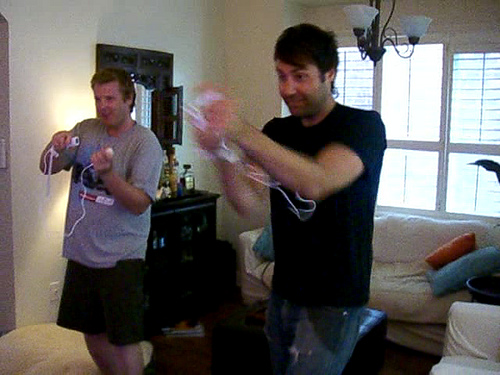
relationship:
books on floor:
[156, 311, 220, 356] [151, 319, 292, 369]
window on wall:
[342, 41, 499, 217] [0, 0, 275, 254]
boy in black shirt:
[39, 66, 164, 374] [254, 100, 389, 310]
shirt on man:
[41, 122, 166, 262] [36, 66, 169, 373]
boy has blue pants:
[199, 43, 434, 356] [261, 293, 367, 371]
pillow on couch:
[422, 230, 479, 269] [210, 137, 497, 332]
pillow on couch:
[422, 246, 498, 298] [210, 137, 497, 332]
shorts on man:
[42, 252, 159, 343] [28, 60, 187, 357]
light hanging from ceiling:
[342, 3, 434, 58] [221, 5, 479, 33]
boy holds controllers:
[27, 59, 184, 372] [28, 124, 120, 176]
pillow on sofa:
[419, 230, 478, 267] [237, 207, 499, 359]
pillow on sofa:
[422, 246, 498, 298] [237, 207, 499, 359]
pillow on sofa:
[252, 215, 277, 261] [237, 207, 499, 359]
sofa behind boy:
[237, 207, 497, 356] [45, 65, 163, 374]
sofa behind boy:
[237, 207, 497, 356] [189, 16, 394, 373]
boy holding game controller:
[193, 22, 386, 373] [181, 83, 241, 156]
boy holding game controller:
[39, 66, 164, 374] [49, 128, 116, 168]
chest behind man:
[144, 187, 224, 339] [36, 66, 169, 373]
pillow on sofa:
[422, 246, 498, 298] [235, 181, 489, 357]